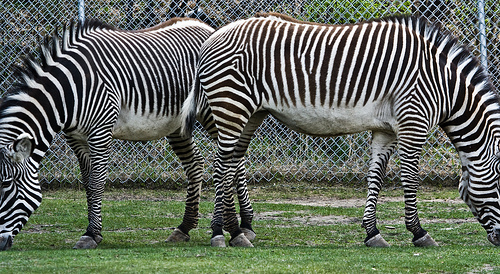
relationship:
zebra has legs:
[194, 8, 500, 251] [208, 119, 439, 247]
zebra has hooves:
[1, 17, 235, 248] [72, 231, 198, 248]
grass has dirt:
[1, 186, 499, 271] [260, 198, 355, 231]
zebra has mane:
[1, 17, 235, 248] [11, 16, 98, 96]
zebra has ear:
[1, 17, 235, 248] [11, 130, 36, 160]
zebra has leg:
[194, 8, 500, 251] [393, 115, 441, 252]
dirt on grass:
[260, 198, 355, 231] [1, 186, 499, 271]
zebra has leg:
[194, 8, 500, 251] [363, 132, 394, 246]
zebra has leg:
[1, 17, 235, 248] [86, 135, 105, 246]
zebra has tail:
[194, 8, 500, 251] [174, 68, 212, 129]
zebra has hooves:
[194, 8, 500, 251] [72, 231, 198, 248]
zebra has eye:
[1, 17, 235, 248] [2, 174, 15, 189]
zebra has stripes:
[194, 8, 500, 251] [194, 23, 446, 129]